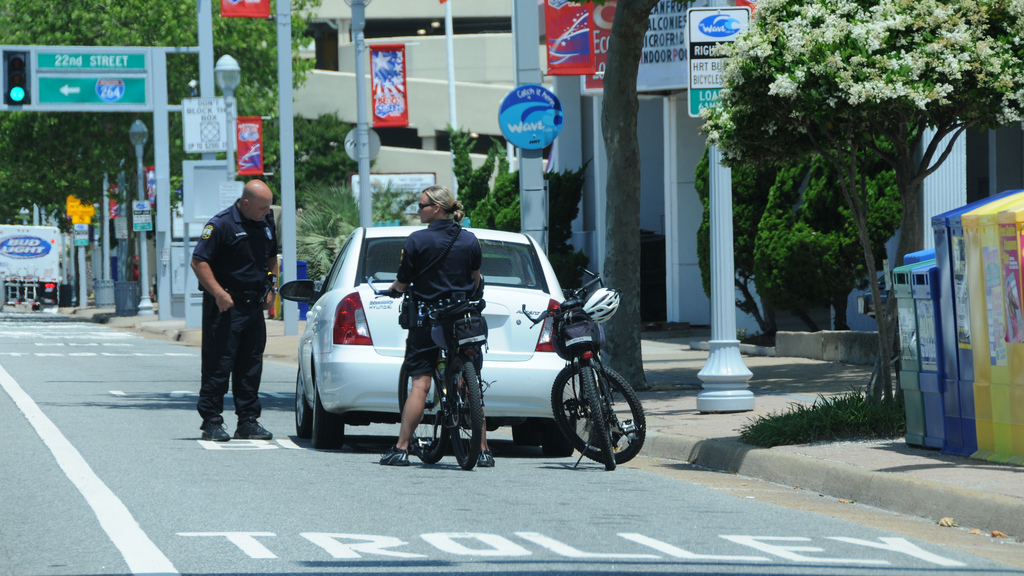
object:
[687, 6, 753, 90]
sign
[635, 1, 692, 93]
sign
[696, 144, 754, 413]
pole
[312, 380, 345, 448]
wheel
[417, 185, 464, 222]
head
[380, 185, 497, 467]
officer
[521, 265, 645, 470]
bike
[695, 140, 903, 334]
tree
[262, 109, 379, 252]
tree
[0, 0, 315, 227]
tree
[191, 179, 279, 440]
policeman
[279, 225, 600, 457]
car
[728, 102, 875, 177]
leaves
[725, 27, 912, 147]
leaves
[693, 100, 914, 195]
leaves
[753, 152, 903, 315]
leaves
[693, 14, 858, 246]
leaves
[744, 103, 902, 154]
leaves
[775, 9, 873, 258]
leaves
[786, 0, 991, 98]
leaves